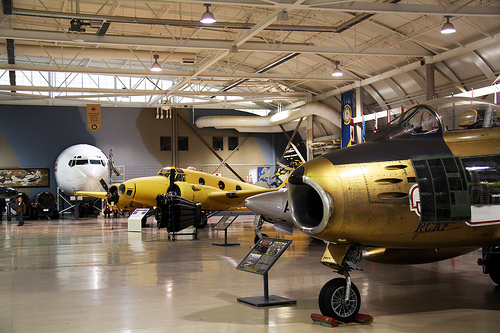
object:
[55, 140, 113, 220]
airplane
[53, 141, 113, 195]
cockpit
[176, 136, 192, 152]
windows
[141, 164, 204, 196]
cockpit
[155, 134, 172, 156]
windows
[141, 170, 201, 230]
propellers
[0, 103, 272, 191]
wall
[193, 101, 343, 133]
tubes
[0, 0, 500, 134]
ceiling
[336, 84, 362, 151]
banner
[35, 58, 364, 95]
rafter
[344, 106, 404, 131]
flags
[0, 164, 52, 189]
frame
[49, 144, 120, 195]
body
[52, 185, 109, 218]
stand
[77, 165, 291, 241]
airplane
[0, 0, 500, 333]
building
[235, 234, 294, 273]
sign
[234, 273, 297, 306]
base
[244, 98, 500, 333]
airplanes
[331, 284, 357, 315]
rim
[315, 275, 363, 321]
wheel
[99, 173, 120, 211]
propeller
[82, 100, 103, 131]
banner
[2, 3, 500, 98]
railing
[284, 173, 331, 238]
trim